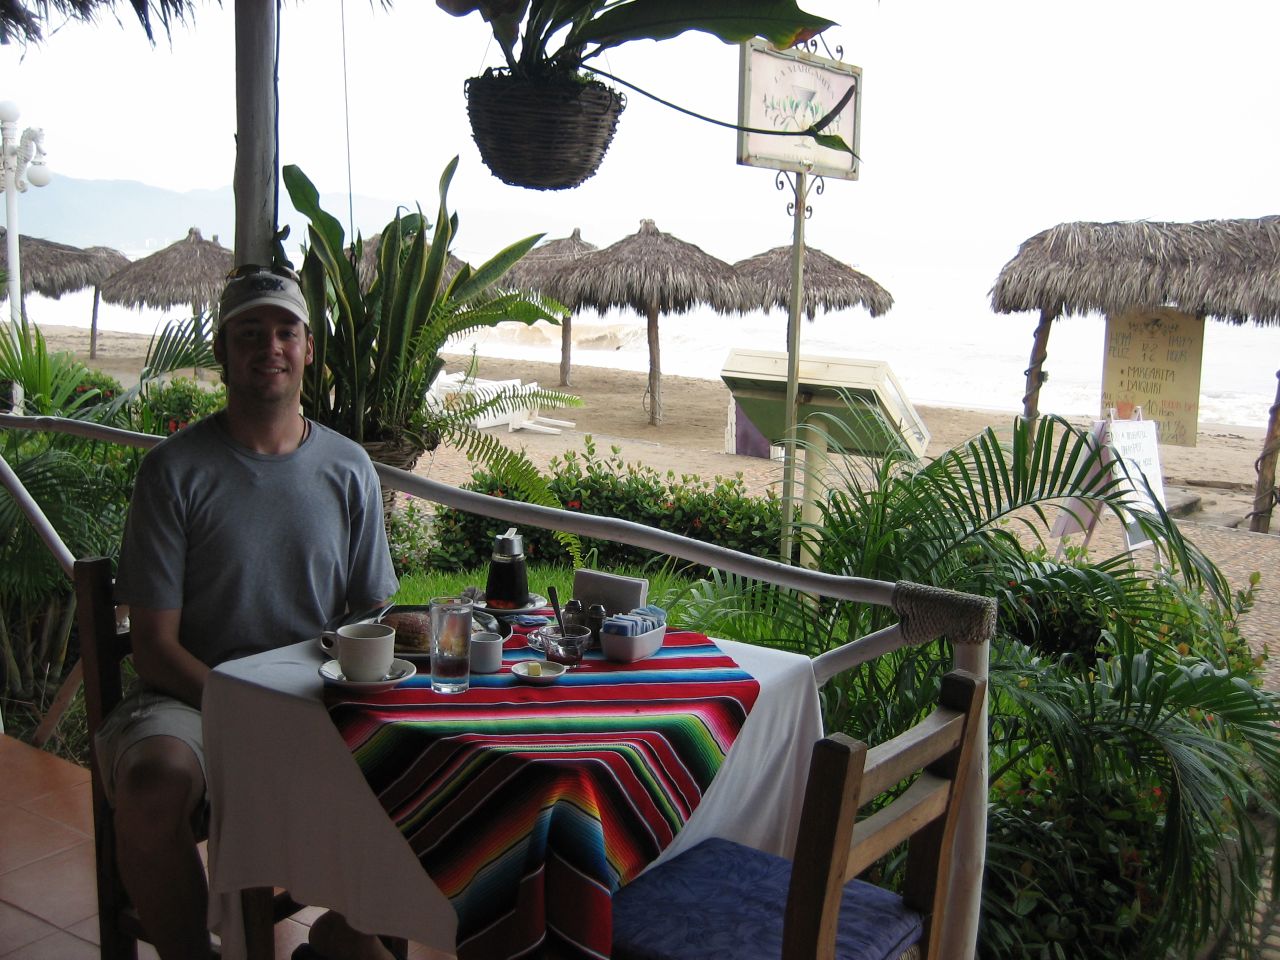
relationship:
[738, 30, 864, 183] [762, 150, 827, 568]
sign on a pole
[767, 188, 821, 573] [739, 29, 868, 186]
pole has a sign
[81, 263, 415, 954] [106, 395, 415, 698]
man wearing shirt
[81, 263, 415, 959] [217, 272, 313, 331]
man wearing cap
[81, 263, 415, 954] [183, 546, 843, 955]
man sitting at table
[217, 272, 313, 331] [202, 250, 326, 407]
cap on head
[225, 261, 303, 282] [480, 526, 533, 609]
sunglasses in a container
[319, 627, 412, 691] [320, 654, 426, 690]
cup on a saucer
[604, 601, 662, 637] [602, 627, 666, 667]
packets in a container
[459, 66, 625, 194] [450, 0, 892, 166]
basket hanging with plant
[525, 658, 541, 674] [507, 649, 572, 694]
butter in dish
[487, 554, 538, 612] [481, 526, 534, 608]
syrup in container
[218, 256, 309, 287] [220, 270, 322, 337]
sunglasses perched on cap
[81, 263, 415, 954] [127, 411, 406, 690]
man in shirt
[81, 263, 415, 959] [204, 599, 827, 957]
man sitting a table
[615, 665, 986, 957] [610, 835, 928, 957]
chair with a seat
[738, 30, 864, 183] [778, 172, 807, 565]
sign on a pole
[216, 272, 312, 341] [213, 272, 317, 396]
cap on mans head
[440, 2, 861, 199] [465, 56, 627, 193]
plant hanging in basket